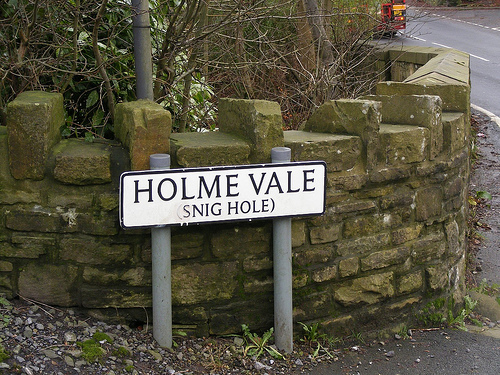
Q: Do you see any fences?
A: No, there are no fences.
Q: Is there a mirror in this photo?
A: No, there are no mirrors.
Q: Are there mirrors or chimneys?
A: No, there are no mirrors or chimneys.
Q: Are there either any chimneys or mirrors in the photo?
A: No, there are no mirrors or chimneys.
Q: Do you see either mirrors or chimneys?
A: No, there are no mirrors or chimneys.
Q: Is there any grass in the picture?
A: Yes, there is grass.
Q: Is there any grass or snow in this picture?
A: Yes, there is grass.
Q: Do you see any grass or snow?
A: Yes, there is grass.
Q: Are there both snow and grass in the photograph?
A: No, there is grass but no snow.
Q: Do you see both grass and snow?
A: No, there is grass but no snow.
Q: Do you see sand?
A: No, there is no sand.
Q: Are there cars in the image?
A: No, there are no cars.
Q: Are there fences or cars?
A: No, there are no cars or fences.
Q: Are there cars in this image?
A: No, there are no cars.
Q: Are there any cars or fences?
A: No, there are no cars or fences.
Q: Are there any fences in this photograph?
A: No, there are no fences.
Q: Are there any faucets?
A: No, there are no faucets.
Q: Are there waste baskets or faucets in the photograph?
A: No, there are no faucets or waste baskets.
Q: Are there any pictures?
A: No, there are no pictures.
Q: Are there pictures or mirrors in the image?
A: No, there are no pictures or mirrors.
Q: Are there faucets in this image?
A: No, there are no faucets.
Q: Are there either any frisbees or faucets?
A: No, there are no faucets or frisbees.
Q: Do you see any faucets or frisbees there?
A: No, there are no faucets or frisbees.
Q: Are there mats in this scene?
A: No, there are no mats.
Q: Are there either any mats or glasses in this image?
A: No, there are no mats or glasses.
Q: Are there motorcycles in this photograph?
A: No, there are no motorcycles.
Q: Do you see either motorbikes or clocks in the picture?
A: No, there are no motorbikes or clocks.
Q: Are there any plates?
A: Yes, there is a plate.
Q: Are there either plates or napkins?
A: Yes, there is a plate.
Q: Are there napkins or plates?
A: Yes, there is a plate.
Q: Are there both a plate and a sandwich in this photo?
A: No, there is a plate but no sandwiches.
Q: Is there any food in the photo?
A: No, there is no food.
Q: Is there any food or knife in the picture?
A: No, there are no food or knives.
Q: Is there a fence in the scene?
A: No, there are no fences.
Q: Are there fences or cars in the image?
A: No, there are no fences or cars.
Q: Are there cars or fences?
A: No, there are no fences or cars.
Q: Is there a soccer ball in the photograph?
A: No, there are no soccer balls.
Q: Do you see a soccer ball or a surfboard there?
A: No, there are no soccer balls or surfboards.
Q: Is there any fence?
A: No, there are no fences.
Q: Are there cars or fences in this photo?
A: No, there are no fences or cars.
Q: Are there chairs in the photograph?
A: No, there are no chairs.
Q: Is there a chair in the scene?
A: No, there are no chairs.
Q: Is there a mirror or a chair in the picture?
A: No, there are no chairs or mirrors.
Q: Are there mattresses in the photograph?
A: No, there are no mattresses.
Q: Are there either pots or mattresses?
A: No, there are no mattresses or pots.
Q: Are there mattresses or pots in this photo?
A: No, there are no mattresses or pots.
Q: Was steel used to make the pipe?
A: Yes, the pipe is made of steel.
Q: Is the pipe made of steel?
A: Yes, the pipe is made of steel.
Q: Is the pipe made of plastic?
A: No, the pipe is made of steel.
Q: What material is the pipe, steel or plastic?
A: The pipe is made of steel.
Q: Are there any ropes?
A: No, there are no ropes.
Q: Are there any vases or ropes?
A: No, there are no ropes or vases.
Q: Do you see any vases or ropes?
A: No, there are no ropes or vases.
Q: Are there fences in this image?
A: No, there are no fences.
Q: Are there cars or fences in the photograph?
A: No, there are no fences or cars.